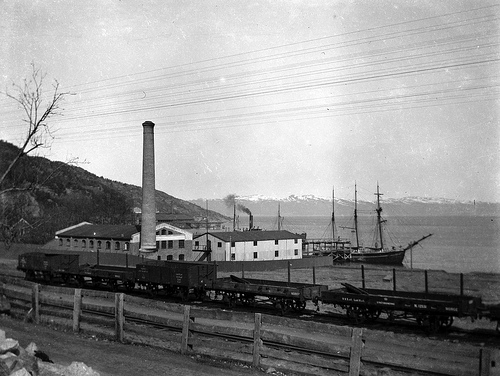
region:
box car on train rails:
[16, 246, 78, 288]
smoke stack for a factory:
[135, 116, 165, 258]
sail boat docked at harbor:
[319, 181, 434, 271]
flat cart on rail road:
[212, 272, 329, 319]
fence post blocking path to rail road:
[170, 299, 202, 358]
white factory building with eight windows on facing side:
[191, 226, 308, 266]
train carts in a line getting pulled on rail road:
[14, 248, 495, 346]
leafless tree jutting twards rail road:
[4, 59, 84, 192]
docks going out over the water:
[298, 234, 358, 261]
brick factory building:
[56, 221, 196, 270]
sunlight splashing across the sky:
[254, 53, 359, 125]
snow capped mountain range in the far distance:
[395, 184, 458, 210]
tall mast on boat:
[339, 179, 402, 257]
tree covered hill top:
[41, 166, 107, 208]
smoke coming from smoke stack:
[220, 193, 260, 225]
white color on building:
[216, 231, 318, 268]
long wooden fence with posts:
[73, 280, 326, 350]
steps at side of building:
[184, 239, 214, 259]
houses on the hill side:
[189, 211, 231, 232]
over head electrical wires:
[201, 66, 410, 118]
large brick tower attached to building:
[128, 104, 175, 300]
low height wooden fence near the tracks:
[94, 277, 204, 355]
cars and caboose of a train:
[13, 235, 480, 359]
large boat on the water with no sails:
[315, 180, 446, 277]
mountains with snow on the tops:
[405, 182, 498, 230]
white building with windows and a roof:
[188, 214, 311, 268]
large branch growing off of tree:
[3, 57, 100, 293]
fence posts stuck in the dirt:
[13, 279, 89, 356]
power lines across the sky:
[146, 57, 279, 135]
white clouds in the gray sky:
[259, 119, 478, 205]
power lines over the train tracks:
[162, 28, 442, 148]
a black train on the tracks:
[19, 247, 482, 349]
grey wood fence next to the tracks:
[135, 298, 356, 375]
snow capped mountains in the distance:
[241, 188, 455, 230]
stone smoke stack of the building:
[130, 118, 167, 255]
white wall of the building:
[224, 240, 299, 267]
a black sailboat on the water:
[310, 183, 422, 270]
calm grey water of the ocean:
[429, 215, 484, 259]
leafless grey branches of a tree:
[1, 78, 88, 265]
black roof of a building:
[221, 228, 281, 243]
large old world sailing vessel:
[308, 182, 436, 269]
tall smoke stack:
[131, 117, 163, 254]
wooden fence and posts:
[0, 271, 498, 373]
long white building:
[191, 225, 308, 265]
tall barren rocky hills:
[1, 137, 228, 254]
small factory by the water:
[45, 116, 307, 285]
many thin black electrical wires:
[0, 10, 496, 145]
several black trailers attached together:
[7, 248, 498, 357]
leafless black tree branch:
[5, 63, 74, 181]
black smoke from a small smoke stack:
[216, 188, 259, 228]